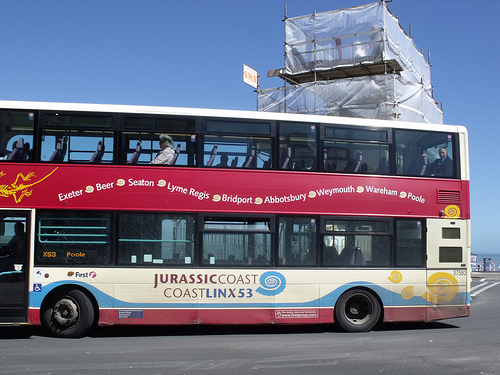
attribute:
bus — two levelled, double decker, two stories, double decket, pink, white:
[1, 100, 472, 337]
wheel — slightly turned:
[40, 287, 96, 339]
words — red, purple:
[153, 275, 258, 290]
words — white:
[57, 177, 427, 208]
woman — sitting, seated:
[152, 135, 176, 165]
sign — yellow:
[424, 273, 459, 304]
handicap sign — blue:
[34, 284, 43, 292]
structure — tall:
[257, 0, 443, 125]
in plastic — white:
[284, 1, 385, 77]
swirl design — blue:
[259, 270, 286, 298]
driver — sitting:
[1, 221, 25, 274]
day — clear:
[1, 0, 500, 128]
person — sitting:
[429, 148, 456, 179]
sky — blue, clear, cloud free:
[1, 0, 500, 129]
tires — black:
[40, 285, 380, 338]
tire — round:
[336, 287, 382, 331]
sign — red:
[1, 163, 472, 219]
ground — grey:
[1, 333, 498, 374]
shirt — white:
[151, 148, 176, 166]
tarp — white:
[284, 1, 386, 75]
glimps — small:
[470, 252, 499, 273]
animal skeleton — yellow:
[0, 163, 59, 209]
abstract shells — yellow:
[389, 271, 459, 307]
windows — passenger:
[36, 209, 427, 270]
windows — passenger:
[1, 108, 461, 180]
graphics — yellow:
[388, 270, 460, 306]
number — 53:
[239, 289, 253, 299]